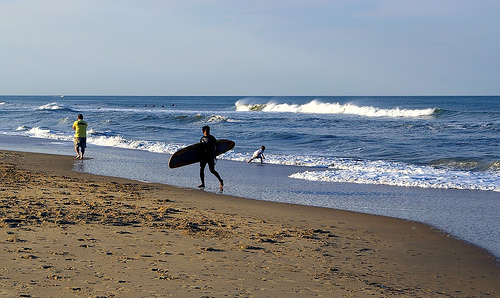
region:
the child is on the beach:
[251, 140, 261, 175]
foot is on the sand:
[242, 195, 336, 270]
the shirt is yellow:
[72, 118, 99, 137]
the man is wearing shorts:
[66, 115, 103, 169]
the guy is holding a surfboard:
[173, 113, 241, 211]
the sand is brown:
[31, 178, 198, 287]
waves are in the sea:
[238, 86, 394, 129]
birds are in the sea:
[131, 87, 189, 119]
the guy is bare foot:
[174, 120, 235, 192]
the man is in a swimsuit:
[152, 120, 247, 187]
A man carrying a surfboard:
[165, 123, 240, 198]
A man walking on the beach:
[68, 111, 92, 164]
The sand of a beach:
[3, 144, 494, 294]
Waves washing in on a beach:
[0, 123, 498, 256]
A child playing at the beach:
[242, 139, 272, 168]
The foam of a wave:
[232, 95, 442, 122]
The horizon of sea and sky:
[2, 85, 499, 102]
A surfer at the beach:
[165, 120, 240, 196]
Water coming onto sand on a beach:
[2, 145, 499, 260]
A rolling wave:
[221, 91, 443, 126]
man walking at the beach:
[41, 100, 125, 197]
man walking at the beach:
[51, 109, 109, 175]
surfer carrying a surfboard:
[185, 122, 248, 210]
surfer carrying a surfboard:
[172, 108, 261, 245]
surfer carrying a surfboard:
[138, 106, 253, 203]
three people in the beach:
[57, 99, 289, 214]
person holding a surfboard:
[164, 119, 241, 196]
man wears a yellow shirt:
[61, 106, 95, 164]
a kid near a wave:
[236, 129, 302, 174]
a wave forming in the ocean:
[39, 85, 488, 125]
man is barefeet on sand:
[63, 105, 93, 161]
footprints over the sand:
[6, 181, 346, 291]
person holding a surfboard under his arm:
[155, 116, 240, 191]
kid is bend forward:
[245, 136, 270, 166]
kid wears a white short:
[241, 136, 273, 173]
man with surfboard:
[166, 112, 235, 194]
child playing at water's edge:
[242, 140, 271, 166]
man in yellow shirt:
[66, 107, 93, 161]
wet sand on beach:
[0, 136, 495, 296]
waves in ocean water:
[3, 86, 496, 208]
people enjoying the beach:
[60, 99, 280, 193]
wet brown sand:
[1, 143, 351, 295]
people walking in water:
[54, 96, 275, 201]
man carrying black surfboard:
[167, 119, 244, 195]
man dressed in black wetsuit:
[169, 124, 238, 197]